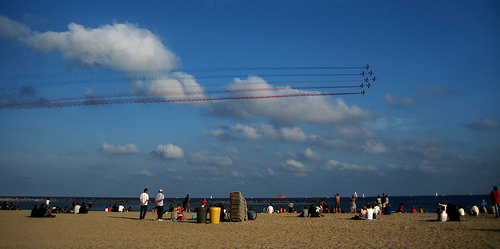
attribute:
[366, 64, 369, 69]
jet — flying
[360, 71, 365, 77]
jet — flying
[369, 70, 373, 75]
jet — flying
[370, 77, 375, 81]
jet — flying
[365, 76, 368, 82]
jet — flying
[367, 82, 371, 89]
jet — flying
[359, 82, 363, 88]
jet — flying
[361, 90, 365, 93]
jet — flying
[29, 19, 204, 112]
cloud — white, fluffy